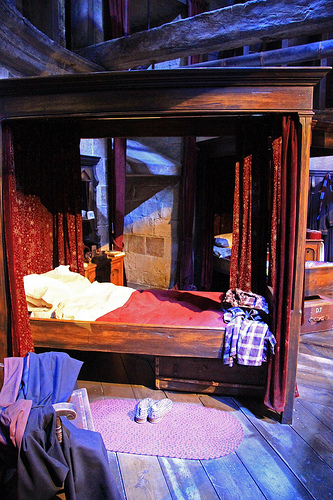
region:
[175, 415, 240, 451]
a pink mat on the floor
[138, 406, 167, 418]
rubber shoes on the mat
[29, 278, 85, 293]
white pillow on the bed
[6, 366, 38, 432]
clothes on the side of the bed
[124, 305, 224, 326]
a red sheet on the bed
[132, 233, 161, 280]
a stony wall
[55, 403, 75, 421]
the arm of a chair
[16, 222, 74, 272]
a red curtain on the side of the bed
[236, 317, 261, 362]
a shirt on the bed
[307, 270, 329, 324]
a rack on the further end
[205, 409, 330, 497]
dark wooden floor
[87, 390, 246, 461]
pink floor rug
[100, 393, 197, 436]
pair of shoes on a rug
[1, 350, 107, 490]
clothes laying on a chair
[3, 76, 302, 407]
antique canopy bed with curtains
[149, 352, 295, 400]
trunk under the bed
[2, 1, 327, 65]
wooden beams on the ceiling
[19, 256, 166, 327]
pillow on the bed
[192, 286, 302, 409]
clothes on the bed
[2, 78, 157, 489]
chair besides the bed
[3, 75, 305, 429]
an old fashioned bed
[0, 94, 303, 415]
the bed is made of wood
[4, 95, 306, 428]
the bed has red curtains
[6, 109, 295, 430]
the curtains are drawn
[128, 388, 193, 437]
a pair of slippers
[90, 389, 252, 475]
a red and blue carpet on the floor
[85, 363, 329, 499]
the floor is wooden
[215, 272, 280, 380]
a plaid robe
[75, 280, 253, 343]
the blanket is red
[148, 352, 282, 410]
there is a trunk underneath the bed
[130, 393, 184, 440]
shoes on a rug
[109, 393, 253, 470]
rug on the floor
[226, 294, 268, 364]
shirt on the bed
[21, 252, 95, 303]
pillow on the bed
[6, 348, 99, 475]
clothes on the chair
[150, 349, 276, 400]
case under the bed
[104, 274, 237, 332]
red blanket on the bed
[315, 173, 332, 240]
clothes hanging in a closet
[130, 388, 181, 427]
plaid shoes on the floor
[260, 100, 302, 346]
drapes on the bed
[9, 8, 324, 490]
set of Harry potter movie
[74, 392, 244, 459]
red rug on wood frame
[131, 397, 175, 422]
boys shoes on red rug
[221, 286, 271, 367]
bathrobe on top of bed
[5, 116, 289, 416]
bed has red curtains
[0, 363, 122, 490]
robes thrown on chair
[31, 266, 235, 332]
bed has red blanket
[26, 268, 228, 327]
bed has white sheets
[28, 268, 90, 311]
bed has white pillows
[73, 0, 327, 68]
ceiling has exposed wood beams